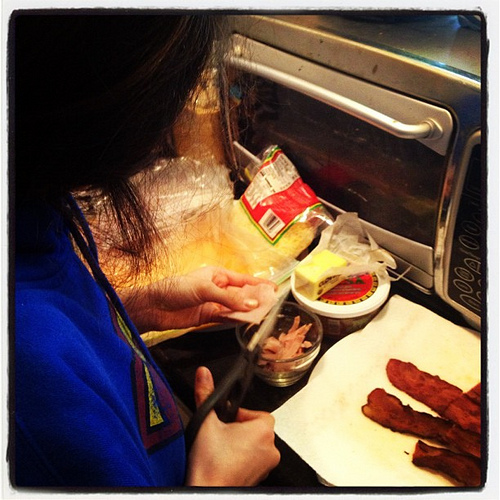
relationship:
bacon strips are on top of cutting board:
[365, 359, 495, 483] [276, 292, 500, 488]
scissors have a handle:
[185, 283, 299, 443] [178, 343, 268, 443]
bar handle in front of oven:
[226, 63, 434, 129] [223, 14, 475, 248]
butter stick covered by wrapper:
[306, 252, 341, 280] [293, 221, 393, 293]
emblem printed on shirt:
[109, 303, 192, 455] [24, 249, 177, 499]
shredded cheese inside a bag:
[230, 245, 253, 269] [160, 144, 336, 275]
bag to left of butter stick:
[160, 144, 336, 275] [306, 252, 341, 280]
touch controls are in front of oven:
[451, 158, 493, 318] [223, 14, 475, 248]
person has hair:
[0, 1, 274, 488] [1, 2, 213, 275]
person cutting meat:
[0, 1, 274, 488] [217, 283, 275, 326]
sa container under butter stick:
[289, 255, 393, 331] [306, 252, 341, 280]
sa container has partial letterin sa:
[289, 255, 393, 331] [346, 270, 367, 294]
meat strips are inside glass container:
[275, 327, 301, 354] [241, 307, 320, 393]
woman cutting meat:
[0, 1, 274, 488] [217, 283, 273, 326]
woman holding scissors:
[0, 1, 274, 488] [185, 283, 299, 443]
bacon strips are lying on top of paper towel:
[365, 359, 495, 483] [276, 292, 500, 488]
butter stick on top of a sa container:
[306, 252, 341, 280] [289, 255, 393, 331]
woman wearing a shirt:
[0, 1, 274, 488] [24, 249, 177, 499]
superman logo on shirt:
[109, 303, 192, 455] [24, 249, 177, 499]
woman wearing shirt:
[0, 1, 274, 488] [24, 249, 177, 499]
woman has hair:
[0, 1, 274, 488] [1, 2, 213, 275]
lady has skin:
[0, 1, 274, 488] [221, 464, 254, 484]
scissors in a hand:
[185, 283, 299, 443] [194, 371, 275, 498]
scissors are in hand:
[185, 283, 299, 443] [194, 371, 275, 498]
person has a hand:
[0, 1, 274, 488] [194, 371, 275, 498]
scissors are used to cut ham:
[185, 283, 299, 443] [217, 283, 275, 326]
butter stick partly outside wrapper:
[306, 252, 341, 280] [293, 221, 393, 293]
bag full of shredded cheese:
[160, 144, 336, 275] [230, 245, 253, 269]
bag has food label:
[160, 144, 336, 275] [244, 161, 317, 239]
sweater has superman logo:
[24, 249, 177, 499] [109, 303, 192, 455]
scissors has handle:
[185, 283, 299, 443] [178, 343, 268, 443]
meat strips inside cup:
[287, 334, 303, 353] [241, 307, 320, 393]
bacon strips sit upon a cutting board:
[365, 359, 495, 483] [276, 292, 500, 488]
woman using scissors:
[0, 1, 274, 488] [185, 283, 299, 443]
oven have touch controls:
[223, 14, 475, 248] [451, 158, 493, 318]